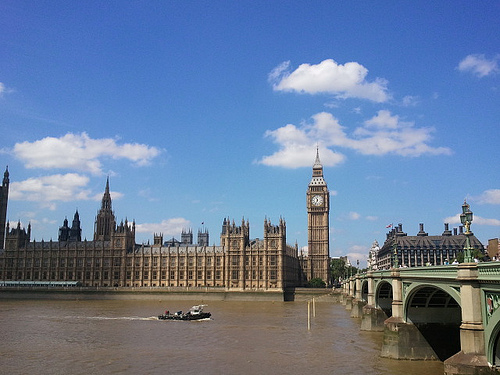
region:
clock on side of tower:
[312, 195, 322, 205]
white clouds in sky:
[14, 129, 156, 179]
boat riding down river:
[158, 305, 213, 325]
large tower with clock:
[306, 139, 329, 291]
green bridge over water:
[341, 238, 499, 373]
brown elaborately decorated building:
[4, 168, 300, 299]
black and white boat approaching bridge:
[153, 301, 210, 323]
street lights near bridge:
[458, 198, 475, 224]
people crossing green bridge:
[441, 258, 458, 266]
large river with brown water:
[12, 292, 344, 372]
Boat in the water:
[154, 300, 215, 324]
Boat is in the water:
[154, 302, 212, 324]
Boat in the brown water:
[155, 303, 214, 323]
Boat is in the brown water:
[152, 301, 217, 326]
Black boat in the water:
[153, 302, 213, 322]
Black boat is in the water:
[155, 300, 211, 323]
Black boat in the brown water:
[151, 302, 211, 322]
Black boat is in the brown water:
[157, 300, 218, 324]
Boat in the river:
[155, 299, 220, 325]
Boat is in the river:
[150, 301, 215, 322]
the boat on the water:
[148, 296, 218, 331]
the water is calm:
[12, 302, 146, 365]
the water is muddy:
[6, 298, 152, 373]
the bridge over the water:
[332, 230, 489, 373]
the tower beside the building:
[289, 138, 345, 288]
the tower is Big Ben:
[304, 143, 342, 288]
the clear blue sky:
[4, 5, 206, 102]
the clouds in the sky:
[277, 59, 395, 115]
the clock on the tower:
[312, 190, 328, 209]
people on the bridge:
[427, 253, 466, 268]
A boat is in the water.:
[149, 297, 216, 327]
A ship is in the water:
[148, 296, 215, 323]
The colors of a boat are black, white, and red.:
[154, 298, 215, 329]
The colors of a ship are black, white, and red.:
[150, 298, 215, 332]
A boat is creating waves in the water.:
[15, 307, 165, 324]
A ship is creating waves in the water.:
[6, 303, 161, 327]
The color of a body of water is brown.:
[0, 290, 455, 371]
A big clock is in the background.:
[307, 190, 329, 210]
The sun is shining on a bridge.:
[333, 249, 498, 374]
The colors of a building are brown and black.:
[0, 164, 302, 294]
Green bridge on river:
[329, 255, 499, 372]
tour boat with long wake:
[27, 291, 220, 326]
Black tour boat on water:
[147, 295, 218, 325]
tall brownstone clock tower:
[303, 139, 333, 297]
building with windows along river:
[7, 171, 289, 311]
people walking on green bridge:
[335, 240, 497, 281]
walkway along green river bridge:
[331, 245, 497, 293]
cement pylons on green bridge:
[330, 267, 499, 374]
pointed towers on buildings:
[1, 157, 301, 252]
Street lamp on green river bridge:
[442, 191, 492, 345]